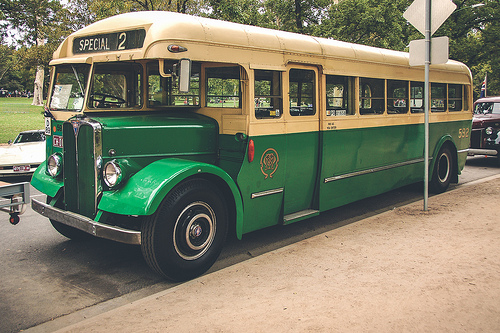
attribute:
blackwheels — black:
[138, 177, 237, 277]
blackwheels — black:
[437, 144, 452, 194]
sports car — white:
[0, 123, 48, 183]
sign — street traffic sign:
[388, 2, 456, 44]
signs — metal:
[403, 1, 459, 216]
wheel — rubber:
[143, 173, 233, 277]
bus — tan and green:
[309, 46, 418, 176]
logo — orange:
[261, 147, 276, 177]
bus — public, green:
[27, 8, 473, 281]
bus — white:
[36, 30, 468, 282]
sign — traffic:
[409, 34, 445, 66]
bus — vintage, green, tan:
[17, 20, 495, 283]